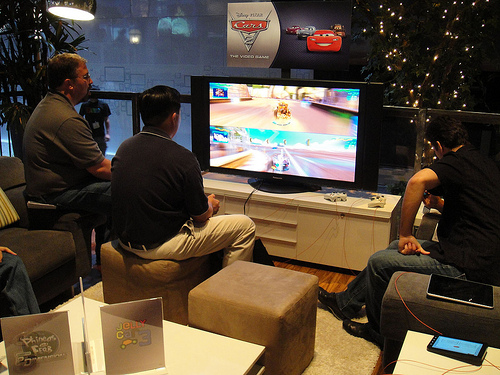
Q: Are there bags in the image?
A: No, there are no bags.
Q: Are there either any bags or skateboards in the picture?
A: No, there are no bags or skateboards.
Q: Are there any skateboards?
A: No, there are no skateboards.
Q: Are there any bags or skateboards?
A: No, there are no skateboards or bags.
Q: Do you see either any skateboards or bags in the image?
A: No, there are no skateboards or bags.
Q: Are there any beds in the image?
A: No, there are no beds.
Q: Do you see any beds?
A: No, there are no beds.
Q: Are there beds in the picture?
A: No, there are no beds.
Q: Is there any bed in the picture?
A: No, there are no beds.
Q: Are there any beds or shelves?
A: No, there are no beds or shelves.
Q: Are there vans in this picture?
A: No, there are no vans.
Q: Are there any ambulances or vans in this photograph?
A: No, there are no vans or ambulances.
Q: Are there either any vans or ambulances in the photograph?
A: No, there are no vans or ambulances.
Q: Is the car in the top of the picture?
A: Yes, the car is in the top of the image.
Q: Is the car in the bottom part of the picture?
A: No, the car is in the top of the image.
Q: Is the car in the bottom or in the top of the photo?
A: The car is in the top of the image.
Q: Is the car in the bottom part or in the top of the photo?
A: The car is in the top of the image.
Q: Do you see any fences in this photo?
A: No, there are no fences.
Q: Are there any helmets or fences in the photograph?
A: No, there are no fences or helmets.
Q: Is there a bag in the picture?
A: No, there are no bags.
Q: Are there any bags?
A: No, there are no bags.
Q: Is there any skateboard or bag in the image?
A: No, there are no bags or skateboards.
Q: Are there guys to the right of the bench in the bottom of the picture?
A: Yes, there is a guy to the right of the bench.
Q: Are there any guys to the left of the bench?
A: No, the guy is to the right of the bench.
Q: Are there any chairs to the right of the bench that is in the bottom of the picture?
A: No, there is a guy to the right of the bench.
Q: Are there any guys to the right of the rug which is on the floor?
A: Yes, there is a guy to the right of the rug.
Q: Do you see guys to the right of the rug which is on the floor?
A: Yes, there is a guy to the right of the rug.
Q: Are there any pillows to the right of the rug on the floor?
A: No, there is a guy to the right of the rug.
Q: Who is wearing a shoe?
A: The guy is wearing a shoe.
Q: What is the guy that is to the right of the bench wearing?
A: The guy is wearing a shoe.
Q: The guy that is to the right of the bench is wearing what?
A: The guy is wearing a shoe.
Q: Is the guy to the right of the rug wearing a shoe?
A: Yes, the guy is wearing a shoe.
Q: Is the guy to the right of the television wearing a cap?
A: No, the guy is wearing a shoe.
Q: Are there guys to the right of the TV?
A: Yes, there is a guy to the right of the TV.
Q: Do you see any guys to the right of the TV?
A: Yes, there is a guy to the right of the TV.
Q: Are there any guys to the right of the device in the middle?
A: Yes, there is a guy to the right of the TV.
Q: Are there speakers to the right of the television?
A: No, there is a guy to the right of the television.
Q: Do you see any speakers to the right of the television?
A: No, there is a guy to the right of the television.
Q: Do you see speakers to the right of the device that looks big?
A: No, there is a guy to the right of the television.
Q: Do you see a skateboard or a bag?
A: No, there are no bags or skateboards.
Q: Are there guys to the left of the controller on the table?
A: Yes, there is a guy to the left of the controller.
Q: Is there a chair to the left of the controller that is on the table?
A: No, there is a guy to the left of the controller.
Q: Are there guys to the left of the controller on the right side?
A: Yes, there is a guy to the left of the controller.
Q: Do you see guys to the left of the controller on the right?
A: Yes, there is a guy to the left of the controller.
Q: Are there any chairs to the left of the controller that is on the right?
A: No, there is a guy to the left of the controller.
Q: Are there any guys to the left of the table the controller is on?
A: Yes, there is a guy to the left of the table.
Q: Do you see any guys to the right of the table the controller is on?
A: No, the guy is to the left of the table.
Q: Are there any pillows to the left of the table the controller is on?
A: No, there is a guy to the left of the table.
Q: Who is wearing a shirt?
A: The guy is wearing a shirt.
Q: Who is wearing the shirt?
A: The guy is wearing a shirt.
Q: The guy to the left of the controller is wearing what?
A: The guy is wearing a shirt.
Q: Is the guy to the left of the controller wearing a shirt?
A: Yes, the guy is wearing a shirt.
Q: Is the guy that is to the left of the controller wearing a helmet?
A: No, the guy is wearing a shirt.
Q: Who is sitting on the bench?
A: The guy is sitting on the bench.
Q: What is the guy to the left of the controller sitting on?
A: The guy is sitting on the bench.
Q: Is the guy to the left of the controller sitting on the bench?
A: Yes, the guy is sitting on the bench.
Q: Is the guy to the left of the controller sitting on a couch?
A: No, the guy is sitting on the bench.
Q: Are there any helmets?
A: No, there are no helmets.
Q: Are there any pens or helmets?
A: No, there are no helmets or pens.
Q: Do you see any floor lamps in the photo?
A: No, there are no floor lamps.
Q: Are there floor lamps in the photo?
A: No, there are no floor lamps.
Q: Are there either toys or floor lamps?
A: No, there are no floor lamps or toys.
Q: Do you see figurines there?
A: No, there are no figurines.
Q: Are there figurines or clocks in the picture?
A: No, there are no figurines or clocks.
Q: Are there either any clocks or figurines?
A: No, there are no figurines or clocks.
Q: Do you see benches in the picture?
A: Yes, there is a bench.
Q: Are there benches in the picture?
A: Yes, there is a bench.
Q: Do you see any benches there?
A: Yes, there is a bench.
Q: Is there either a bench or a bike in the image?
A: Yes, there is a bench.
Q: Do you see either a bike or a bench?
A: Yes, there is a bench.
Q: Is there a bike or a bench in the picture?
A: Yes, there is a bench.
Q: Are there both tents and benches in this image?
A: No, there is a bench but no tents.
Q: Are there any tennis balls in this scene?
A: No, there are no tennis balls.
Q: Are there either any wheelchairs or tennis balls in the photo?
A: No, there are no tennis balls or wheelchairs.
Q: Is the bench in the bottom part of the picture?
A: Yes, the bench is in the bottom of the image.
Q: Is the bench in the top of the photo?
A: No, the bench is in the bottom of the image.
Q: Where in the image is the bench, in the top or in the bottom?
A: The bench is in the bottom of the image.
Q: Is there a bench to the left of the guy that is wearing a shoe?
A: Yes, there is a bench to the left of the guy.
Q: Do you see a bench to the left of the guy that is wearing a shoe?
A: Yes, there is a bench to the left of the guy.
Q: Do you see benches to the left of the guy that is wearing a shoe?
A: Yes, there is a bench to the left of the guy.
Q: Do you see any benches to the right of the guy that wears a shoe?
A: No, the bench is to the left of the guy.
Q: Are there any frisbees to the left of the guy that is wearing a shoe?
A: No, there is a bench to the left of the guy.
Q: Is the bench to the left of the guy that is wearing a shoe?
A: Yes, the bench is to the left of the guy.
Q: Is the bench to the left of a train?
A: No, the bench is to the left of the guy.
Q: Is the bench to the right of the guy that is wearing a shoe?
A: No, the bench is to the left of the guy.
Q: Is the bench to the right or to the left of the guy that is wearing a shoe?
A: The bench is to the left of the guy.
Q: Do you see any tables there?
A: Yes, there is a table.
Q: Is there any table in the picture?
A: Yes, there is a table.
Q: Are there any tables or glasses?
A: Yes, there is a table.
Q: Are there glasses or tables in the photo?
A: Yes, there is a table.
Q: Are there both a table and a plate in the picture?
A: No, there is a table but no plates.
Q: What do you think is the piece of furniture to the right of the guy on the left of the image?
A: The piece of furniture is a table.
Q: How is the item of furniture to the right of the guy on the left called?
A: The piece of furniture is a table.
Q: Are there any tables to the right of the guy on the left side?
A: Yes, there is a table to the right of the guy.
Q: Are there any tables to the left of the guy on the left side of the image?
A: No, the table is to the right of the guy.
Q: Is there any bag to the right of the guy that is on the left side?
A: No, there is a table to the right of the guy.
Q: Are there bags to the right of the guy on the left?
A: No, there is a table to the right of the guy.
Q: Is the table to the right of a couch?
A: No, the table is to the right of a guy.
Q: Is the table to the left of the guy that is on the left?
A: No, the table is to the right of the guy.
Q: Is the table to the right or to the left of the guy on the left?
A: The table is to the right of the guy.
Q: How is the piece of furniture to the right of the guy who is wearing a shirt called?
A: The piece of furniture is a table.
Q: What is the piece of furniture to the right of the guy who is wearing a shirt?
A: The piece of furniture is a table.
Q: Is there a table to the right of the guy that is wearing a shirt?
A: Yes, there is a table to the right of the guy.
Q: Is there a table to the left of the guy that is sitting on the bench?
A: No, the table is to the right of the guy.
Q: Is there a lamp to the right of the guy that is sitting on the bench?
A: No, there is a table to the right of the guy.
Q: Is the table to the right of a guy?
A: Yes, the table is to the right of a guy.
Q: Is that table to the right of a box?
A: No, the table is to the right of a guy.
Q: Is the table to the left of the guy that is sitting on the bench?
A: No, the table is to the right of the guy.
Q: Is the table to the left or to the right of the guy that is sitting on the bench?
A: The table is to the right of the guy.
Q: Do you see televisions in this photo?
A: Yes, there is a television.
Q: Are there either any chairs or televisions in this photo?
A: Yes, there is a television.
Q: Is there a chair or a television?
A: Yes, there is a television.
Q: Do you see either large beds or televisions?
A: Yes, there is a large television.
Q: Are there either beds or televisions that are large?
A: Yes, the television is large.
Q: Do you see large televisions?
A: Yes, there is a large television.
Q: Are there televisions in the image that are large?
A: Yes, there is a television that is large.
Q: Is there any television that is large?
A: Yes, there is a television that is large.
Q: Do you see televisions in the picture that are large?
A: Yes, there is a television that is large.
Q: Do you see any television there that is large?
A: Yes, there is a television that is large.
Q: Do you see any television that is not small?
A: Yes, there is a large television.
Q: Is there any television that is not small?
A: Yes, there is a large television.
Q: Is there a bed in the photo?
A: No, there are no beds.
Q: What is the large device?
A: The device is a television.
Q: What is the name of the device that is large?
A: The device is a television.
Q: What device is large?
A: The device is a television.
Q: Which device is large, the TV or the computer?
A: The TV is large.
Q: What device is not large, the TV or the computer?
A: The computer is not large.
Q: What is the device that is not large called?
A: The device is a computer.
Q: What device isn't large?
A: The device is a computer.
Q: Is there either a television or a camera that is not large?
A: No, there is a television but it is large.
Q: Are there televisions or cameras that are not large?
A: No, there is a television but it is large.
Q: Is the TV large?
A: Yes, the TV is large.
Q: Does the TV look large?
A: Yes, the TV is large.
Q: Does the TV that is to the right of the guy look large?
A: Yes, the TV is large.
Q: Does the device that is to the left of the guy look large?
A: Yes, the TV is large.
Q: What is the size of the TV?
A: The TV is large.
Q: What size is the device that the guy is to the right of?
A: The TV is large.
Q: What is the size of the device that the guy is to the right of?
A: The TV is large.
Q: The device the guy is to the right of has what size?
A: The TV is large.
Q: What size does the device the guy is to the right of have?
A: The TV has large size.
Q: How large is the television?
A: The television is large.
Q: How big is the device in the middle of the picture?
A: The television is large.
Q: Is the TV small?
A: No, the TV is large.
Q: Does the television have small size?
A: No, the television is large.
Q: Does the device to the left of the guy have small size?
A: No, the television is large.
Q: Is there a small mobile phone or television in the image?
A: No, there is a television but it is large.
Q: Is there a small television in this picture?
A: No, there is a television but it is large.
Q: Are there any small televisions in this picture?
A: No, there is a television but it is large.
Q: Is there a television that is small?
A: No, there is a television but it is large.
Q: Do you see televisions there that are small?
A: No, there is a television but it is large.